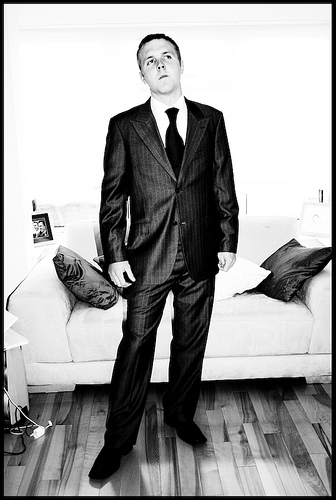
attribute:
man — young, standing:
[86, 32, 243, 481]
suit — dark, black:
[99, 94, 243, 449]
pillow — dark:
[260, 235, 330, 301]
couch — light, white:
[8, 197, 330, 393]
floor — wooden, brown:
[4, 376, 334, 498]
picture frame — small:
[30, 211, 53, 242]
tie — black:
[163, 105, 187, 175]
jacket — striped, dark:
[99, 94, 245, 286]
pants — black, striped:
[101, 239, 220, 450]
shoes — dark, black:
[85, 406, 209, 483]